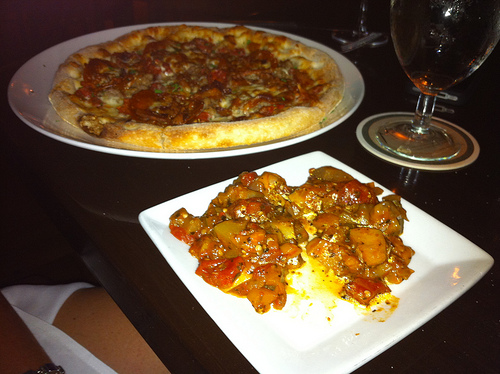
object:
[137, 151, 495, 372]
plate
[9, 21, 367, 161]
plate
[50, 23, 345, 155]
pizza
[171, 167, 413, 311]
food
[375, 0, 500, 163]
glass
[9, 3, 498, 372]
table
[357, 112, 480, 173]
coaster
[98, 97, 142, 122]
sauce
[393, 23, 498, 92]
wine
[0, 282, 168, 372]
person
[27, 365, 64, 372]
wrist watch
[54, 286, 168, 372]
thigh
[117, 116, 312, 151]
crust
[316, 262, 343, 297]
sauce